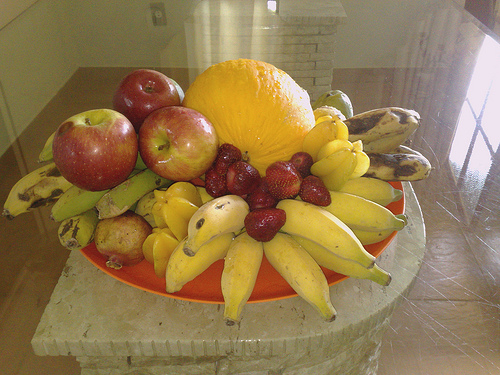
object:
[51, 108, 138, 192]
apple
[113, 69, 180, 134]
apple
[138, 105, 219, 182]
apple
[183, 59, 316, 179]
orange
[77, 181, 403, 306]
bowl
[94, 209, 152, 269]
pomegranate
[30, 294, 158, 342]
table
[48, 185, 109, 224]
bananas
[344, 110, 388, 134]
mark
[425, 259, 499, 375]
ground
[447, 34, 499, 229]
windows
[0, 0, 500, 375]
building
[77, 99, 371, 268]
pile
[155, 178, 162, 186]
spot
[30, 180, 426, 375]
table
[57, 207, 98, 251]
bananas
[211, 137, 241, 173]
strawberries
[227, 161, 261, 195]
strawberries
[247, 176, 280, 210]
strawberries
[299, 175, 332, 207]
strawberries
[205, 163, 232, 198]
strawberries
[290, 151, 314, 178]
strawberries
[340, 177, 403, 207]
bananas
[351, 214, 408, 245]
bananas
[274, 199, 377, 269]
bananas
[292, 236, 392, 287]
bananas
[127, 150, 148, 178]
bananas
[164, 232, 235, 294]
bananas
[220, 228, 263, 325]
bananas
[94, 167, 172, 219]
bananas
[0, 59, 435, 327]
fruit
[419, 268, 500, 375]
tiles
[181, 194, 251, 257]
banana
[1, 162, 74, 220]
banana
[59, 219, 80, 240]
mark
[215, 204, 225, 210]
mark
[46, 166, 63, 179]
mark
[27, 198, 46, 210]
mark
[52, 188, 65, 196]
mark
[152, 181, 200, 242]
starfruit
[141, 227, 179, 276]
starfruit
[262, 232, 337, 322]
bananas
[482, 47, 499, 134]
sunlight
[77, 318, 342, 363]
table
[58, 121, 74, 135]
spot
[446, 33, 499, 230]
glass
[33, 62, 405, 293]
fruit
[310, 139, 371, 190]
starfruit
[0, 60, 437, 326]
arrangement